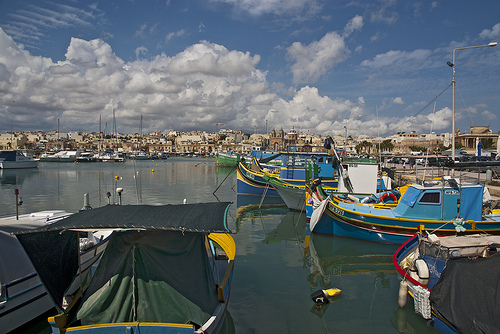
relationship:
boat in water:
[318, 186, 496, 262] [236, 245, 306, 306]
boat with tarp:
[318, 186, 496, 262] [96, 243, 233, 333]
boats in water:
[230, 157, 484, 272] [236, 245, 306, 306]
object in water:
[293, 294, 400, 325] [236, 245, 306, 306]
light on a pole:
[6, 178, 29, 235] [451, 96, 464, 176]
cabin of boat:
[407, 193, 451, 220] [318, 186, 496, 262]